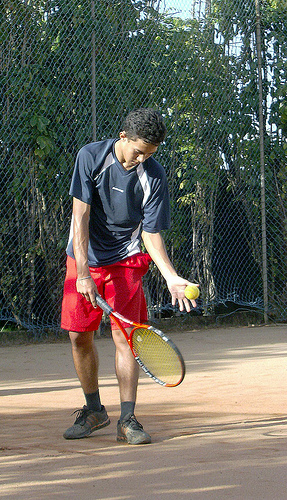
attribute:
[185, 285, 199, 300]
ball — yellow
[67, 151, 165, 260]
shirt — gray, white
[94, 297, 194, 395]
racket — black, orange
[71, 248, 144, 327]
shorts — Red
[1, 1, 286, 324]
fence — broken, metal, grey, chain link, chain-link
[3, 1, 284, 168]
sky — blue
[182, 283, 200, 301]
ball — Yellow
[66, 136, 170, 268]
t-shirt — blue, grey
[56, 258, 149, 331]
shorts — red, cotton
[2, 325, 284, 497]
ground — Tan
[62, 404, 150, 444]
sneakers — orange, black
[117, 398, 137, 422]
sock — gray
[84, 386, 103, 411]
sock — gray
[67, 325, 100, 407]
leg — hairy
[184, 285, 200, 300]
tennis ball — yellow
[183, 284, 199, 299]
tennis ball — small, yellow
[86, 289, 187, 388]
tennis racket — orange, Black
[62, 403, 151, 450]
tennis shoes — Black, orange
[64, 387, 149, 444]
shoes — black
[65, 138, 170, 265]
shirt — black, blue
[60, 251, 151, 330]
shorts — red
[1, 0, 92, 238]
trees — chain-link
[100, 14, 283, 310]
leaves — green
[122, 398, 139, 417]
sock —  black